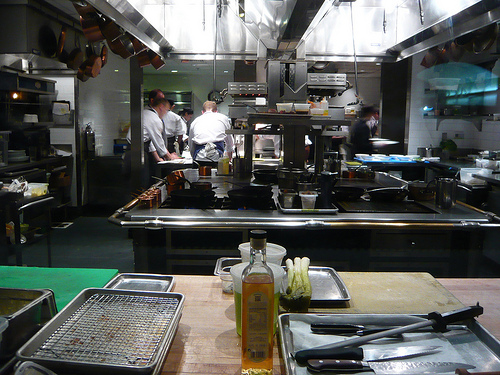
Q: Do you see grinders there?
A: No, there are no grinders.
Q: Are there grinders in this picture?
A: No, there are no grinders.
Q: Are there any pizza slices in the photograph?
A: No, there are no pizza slices.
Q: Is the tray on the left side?
A: Yes, the tray is on the left of the image.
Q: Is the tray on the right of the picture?
A: No, the tray is on the left of the image.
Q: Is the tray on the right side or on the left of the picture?
A: The tray is on the left of the image.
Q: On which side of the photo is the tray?
A: The tray is on the left of the image.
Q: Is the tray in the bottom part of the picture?
A: Yes, the tray is in the bottom of the image.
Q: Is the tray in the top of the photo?
A: No, the tray is in the bottom of the image.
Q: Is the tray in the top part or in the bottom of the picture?
A: The tray is in the bottom of the image.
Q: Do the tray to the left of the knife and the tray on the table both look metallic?
A: Yes, both the tray and the tray are metallic.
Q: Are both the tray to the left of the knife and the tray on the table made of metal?
A: Yes, both the tray and the tray are made of metal.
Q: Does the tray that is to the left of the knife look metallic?
A: Yes, the tray is metallic.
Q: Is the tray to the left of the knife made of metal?
A: Yes, the tray is made of metal.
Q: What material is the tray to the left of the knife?
A: The tray is made of metal.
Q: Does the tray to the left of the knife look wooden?
A: No, the tray is metallic.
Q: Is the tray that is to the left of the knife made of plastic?
A: No, the tray is made of metal.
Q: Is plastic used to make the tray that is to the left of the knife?
A: No, the tray is made of metal.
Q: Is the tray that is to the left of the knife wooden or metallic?
A: The tray is metallic.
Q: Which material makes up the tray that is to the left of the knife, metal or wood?
A: The tray is made of metal.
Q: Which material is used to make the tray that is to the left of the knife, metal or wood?
A: The tray is made of metal.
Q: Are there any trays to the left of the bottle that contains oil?
A: Yes, there is a tray to the left of the bottle.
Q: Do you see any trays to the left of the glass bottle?
A: Yes, there is a tray to the left of the bottle.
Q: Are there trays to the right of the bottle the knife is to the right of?
A: No, the tray is to the left of the bottle.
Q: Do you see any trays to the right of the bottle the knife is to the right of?
A: No, the tray is to the left of the bottle.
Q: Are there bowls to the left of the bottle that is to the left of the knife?
A: No, there is a tray to the left of the bottle.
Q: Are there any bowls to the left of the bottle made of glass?
A: No, there is a tray to the left of the bottle.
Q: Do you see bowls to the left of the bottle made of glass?
A: No, there is a tray to the left of the bottle.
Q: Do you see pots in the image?
A: Yes, there is a pot.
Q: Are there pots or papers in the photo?
A: Yes, there is a pot.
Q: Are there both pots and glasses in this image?
A: No, there is a pot but no glasses.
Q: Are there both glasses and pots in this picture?
A: No, there is a pot but no glasses.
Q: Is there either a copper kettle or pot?
A: Yes, there is a copper pot.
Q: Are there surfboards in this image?
A: No, there are no surfboards.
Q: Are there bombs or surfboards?
A: No, there are no surfboards or bombs.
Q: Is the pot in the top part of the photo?
A: Yes, the pot is in the top of the image.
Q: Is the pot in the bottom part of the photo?
A: No, the pot is in the top of the image.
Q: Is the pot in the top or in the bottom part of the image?
A: The pot is in the top of the image.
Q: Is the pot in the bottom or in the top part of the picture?
A: The pot is in the top of the image.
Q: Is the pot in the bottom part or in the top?
A: The pot is in the top of the image.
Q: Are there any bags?
A: No, there are no bags.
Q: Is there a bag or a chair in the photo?
A: No, there are no bags or chairs.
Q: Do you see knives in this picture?
A: Yes, there is a knife.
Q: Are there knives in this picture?
A: Yes, there is a knife.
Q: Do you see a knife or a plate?
A: Yes, there is a knife.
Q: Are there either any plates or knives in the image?
A: Yes, there is a knife.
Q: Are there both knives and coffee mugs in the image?
A: No, there is a knife but no coffee mugs.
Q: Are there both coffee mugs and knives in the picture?
A: No, there is a knife but no coffee mugs.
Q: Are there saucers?
A: No, there are no saucers.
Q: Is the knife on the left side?
A: No, the knife is on the right of the image.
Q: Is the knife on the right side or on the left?
A: The knife is on the right of the image.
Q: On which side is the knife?
A: The knife is on the right of the image.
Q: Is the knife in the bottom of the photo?
A: Yes, the knife is in the bottom of the image.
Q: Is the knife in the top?
A: No, the knife is in the bottom of the image.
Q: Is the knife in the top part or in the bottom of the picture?
A: The knife is in the bottom of the image.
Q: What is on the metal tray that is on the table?
A: The knife is on the tray.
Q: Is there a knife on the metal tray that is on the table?
A: Yes, there is a knife on the tray.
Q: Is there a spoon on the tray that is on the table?
A: No, there is a knife on the tray.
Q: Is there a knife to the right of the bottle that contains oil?
A: Yes, there is a knife to the right of the bottle.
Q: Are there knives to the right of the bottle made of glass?
A: Yes, there is a knife to the right of the bottle.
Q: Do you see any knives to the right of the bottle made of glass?
A: Yes, there is a knife to the right of the bottle.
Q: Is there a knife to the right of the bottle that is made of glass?
A: Yes, there is a knife to the right of the bottle.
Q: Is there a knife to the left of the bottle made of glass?
A: No, the knife is to the right of the bottle.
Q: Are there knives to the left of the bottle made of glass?
A: No, the knife is to the right of the bottle.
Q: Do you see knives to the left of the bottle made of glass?
A: No, the knife is to the right of the bottle.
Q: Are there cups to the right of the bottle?
A: No, there is a knife to the right of the bottle.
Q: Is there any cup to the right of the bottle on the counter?
A: No, there is a knife to the right of the bottle.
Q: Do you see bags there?
A: No, there are no bags.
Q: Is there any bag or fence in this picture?
A: No, there are no bags or fences.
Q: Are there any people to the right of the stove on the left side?
A: Yes, there is a person to the right of the stove.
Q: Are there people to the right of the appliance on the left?
A: Yes, there is a person to the right of the stove.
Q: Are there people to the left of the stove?
A: No, the person is to the right of the stove.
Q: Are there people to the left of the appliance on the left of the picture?
A: No, the person is to the right of the stove.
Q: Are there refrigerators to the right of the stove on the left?
A: No, there is a person to the right of the stove.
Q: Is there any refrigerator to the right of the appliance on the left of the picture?
A: No, there is a person to the right of the stove.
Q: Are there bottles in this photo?
A: Yes, there is a bottle.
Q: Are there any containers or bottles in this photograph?
A: Yes, there is a bottle.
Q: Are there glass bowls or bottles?
A: Yes, there is a glass bottle.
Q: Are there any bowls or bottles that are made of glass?
A: Yes, the bottle is made of glass.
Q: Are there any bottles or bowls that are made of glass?
A: Yes, the bottle is made of glass.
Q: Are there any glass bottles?
A: Yes, there is a bottle that is made of glass.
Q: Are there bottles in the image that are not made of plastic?
A: Yes, there is a bottle that is made of glass.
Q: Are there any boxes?
A: No, there are no boxes.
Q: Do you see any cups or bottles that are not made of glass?
A: No, there is a bottle but it is made of glass.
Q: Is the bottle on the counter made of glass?
A: Yes, the bottle is made of glass.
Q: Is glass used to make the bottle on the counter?
A: Yes, the bottle is made of glass.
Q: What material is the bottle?
A: The bottle is made of glass.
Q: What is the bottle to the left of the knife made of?
A: The bottle is made of glass.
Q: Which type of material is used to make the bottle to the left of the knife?
A: The bottle is made of glass.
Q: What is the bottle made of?
A: The bottle is made of glass.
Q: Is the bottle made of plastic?
A: No, the bottle is made of glass.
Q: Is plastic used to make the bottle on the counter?
A: No, the bottle is made of glass.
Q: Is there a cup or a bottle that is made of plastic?
A: No, there is a bottle but it is made of glass.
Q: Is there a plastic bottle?
A: No, there is a bottle but it is made of glass.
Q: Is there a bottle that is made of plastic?
A: No, there is a bottle but it is made of glass.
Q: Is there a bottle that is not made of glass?
A: No, there is a bottle but it is made of glass.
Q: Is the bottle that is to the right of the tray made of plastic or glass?
A: The bottle is made of glass.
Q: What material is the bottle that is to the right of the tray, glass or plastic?
A: The bottle is made of glass.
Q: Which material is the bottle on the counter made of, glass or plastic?
A: The bottle is made of glass.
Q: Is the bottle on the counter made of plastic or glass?
A: The bottle is made of glass.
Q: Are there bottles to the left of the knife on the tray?
A: Yes, there is a bottle to the left of the knife.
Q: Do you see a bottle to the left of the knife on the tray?
A: Yes, there is a bottle to the left of the knife.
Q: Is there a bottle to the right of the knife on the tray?
A: No, the bottle is to the left of the knife.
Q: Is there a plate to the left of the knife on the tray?
A: No, there is a bottle to the left of the knife.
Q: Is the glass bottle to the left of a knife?
A: Yes, the bottle is to the left of a knife.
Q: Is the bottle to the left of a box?
A: No, the bottle is to the left of a knife.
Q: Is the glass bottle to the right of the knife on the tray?
A: No, the bottle is to the left of the knife.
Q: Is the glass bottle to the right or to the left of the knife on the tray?
A: The bottle is to the left of the knife.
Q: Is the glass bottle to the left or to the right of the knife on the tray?
A: The bottle is to the left of the knife.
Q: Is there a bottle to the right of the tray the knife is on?
A: Yes, there is a bottle to the right of the tray.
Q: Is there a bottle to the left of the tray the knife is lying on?
A: No, the bottle is to the right of the tray.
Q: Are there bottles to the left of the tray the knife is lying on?
A: No, the bottle is to the right of the tray.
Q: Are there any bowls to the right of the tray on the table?
A: No, there is a bottle to the right of the tray.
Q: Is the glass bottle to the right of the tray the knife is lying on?
A: Yes, the bottle is to the right of the tray.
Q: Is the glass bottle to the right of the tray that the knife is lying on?
A: Yes, the bottle is to the right of the tray.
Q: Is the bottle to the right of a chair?
A: No, the bottle is to the right of the tray.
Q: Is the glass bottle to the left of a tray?
A: No, the bottle is to the right of a tray.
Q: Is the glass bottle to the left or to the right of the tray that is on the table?
A: The bottle is to the right of the tray.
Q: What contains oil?
A: The bottle contains oil.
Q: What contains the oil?
A: The bottle contains oil.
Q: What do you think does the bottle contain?
A: The bottle contains oil.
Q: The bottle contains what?
A: The bottle contains oil.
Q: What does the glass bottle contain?
A: The bottle contains oil.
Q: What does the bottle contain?
A: The bottle contains oil.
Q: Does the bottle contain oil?
A: Yes, the bottle contains oil.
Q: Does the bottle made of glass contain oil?
A: Yes, the bottle contains oil.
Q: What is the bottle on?
A: The bottle is on the counter.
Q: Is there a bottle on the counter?
A: Yes, there is a bottle on the counter.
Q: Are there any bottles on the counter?
A: Yes, there is a bottle on the counter.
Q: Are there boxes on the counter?
A: No, there is a bottle on the counter.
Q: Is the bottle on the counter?
A: Yes, the bottle is on the counter.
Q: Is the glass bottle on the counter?
A: Yes, the bottle is on the counter.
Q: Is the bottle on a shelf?
A: No, the bottle is on the counter.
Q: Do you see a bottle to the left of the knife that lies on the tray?
A: Yes, there is a bottle to the left of the knife.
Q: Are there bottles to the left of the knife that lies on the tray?
A: Yes, there is a bottle to the left of the knife.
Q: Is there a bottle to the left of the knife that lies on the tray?
A: Yes, there is a bottle to the left of the knife.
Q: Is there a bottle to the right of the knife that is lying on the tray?
A: No, the bottle is to the left of the knife.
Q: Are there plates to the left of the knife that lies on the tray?
A: No, there is a bottle to the left of the knife.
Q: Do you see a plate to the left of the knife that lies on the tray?
A: No, there is a bottle to the left of the knife.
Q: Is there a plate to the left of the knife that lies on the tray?
A: No, there is a bottle to the left of the knife.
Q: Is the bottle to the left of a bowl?
A: No, the bottle is to the left of a knife.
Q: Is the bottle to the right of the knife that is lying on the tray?
A: No, the bottle is to the left of the knife.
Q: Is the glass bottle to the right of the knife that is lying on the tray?
A: No, the bottle is to the left of the knife.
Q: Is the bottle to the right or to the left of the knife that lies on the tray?
A: The bottle is to the left of the knife.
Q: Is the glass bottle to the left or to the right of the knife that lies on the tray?
A: The bottle is to the left of the knife.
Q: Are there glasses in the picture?
A: No, there are no glasses.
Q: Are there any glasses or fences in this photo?
A: No, there are no glasses or fences.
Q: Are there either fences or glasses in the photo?
A: No, there are no glasses or fences.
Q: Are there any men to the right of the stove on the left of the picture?
A: Yes, there is a man to the right of the stove.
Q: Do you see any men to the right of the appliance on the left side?
A: Yes, there is a man to the right of the stove.